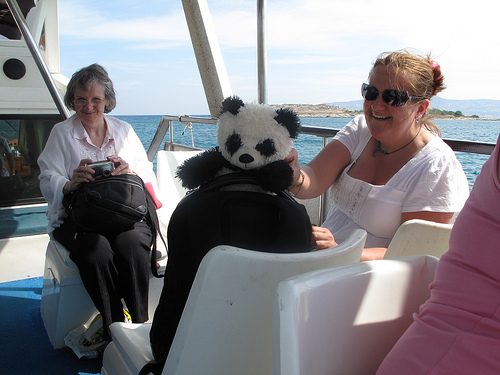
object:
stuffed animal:
[174, 95, 300, 194]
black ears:
[219, 94, 245, 116]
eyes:
[224, 130, 243, 157]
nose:
[238, 153, 255, 164]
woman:
[37, 62, 162, 344]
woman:
[283, 52, 473, 260]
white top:
[312, 115, 470, 257]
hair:
[64, 63, 117, 114]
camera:
[83, 159, 116, 180]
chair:
[98, 228, 370, 374]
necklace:
[373, 120, 423, 156]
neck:
[369, 115, 427, 152]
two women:
[36, 50, 471, 343]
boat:
[1, 0, 500, 375]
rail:
[145, 114, 496, 163]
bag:
[62, 170, 147, 235]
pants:
[54, 209, 157, 341]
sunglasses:
[360, 82, 431, 108]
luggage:
[148, 172, 314, 373]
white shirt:
[37, 113, 157, 235]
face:
[74, 84, 106, 124]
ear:
[413, 98, 430, 120]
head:
[216, 93, 302, 170]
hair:
[367, 48, 445, 137]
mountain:
[260, 104, 499, 121]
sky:
[56, 0, 500, 116]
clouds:
[57, 3, 95, 31]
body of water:
[108, 115, 500, 209]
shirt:
[372, 135, 498, 374]